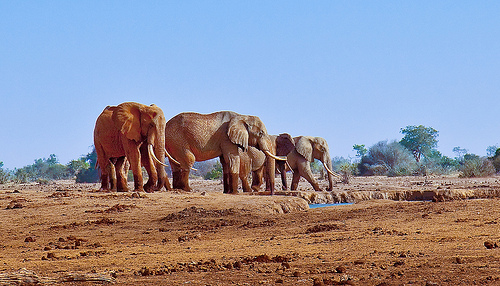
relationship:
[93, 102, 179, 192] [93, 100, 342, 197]
elephant in herd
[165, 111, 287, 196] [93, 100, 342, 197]
elephant in herd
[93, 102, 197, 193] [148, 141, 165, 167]
elephant has tusk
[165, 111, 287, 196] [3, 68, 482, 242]
elephant in jungle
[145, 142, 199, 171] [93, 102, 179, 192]
tusk of an elephant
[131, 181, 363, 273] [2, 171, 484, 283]
dirt on ground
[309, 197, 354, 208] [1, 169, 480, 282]
water in middle of desert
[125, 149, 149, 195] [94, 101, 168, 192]
leg of an elephant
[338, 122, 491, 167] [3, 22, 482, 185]
trees in background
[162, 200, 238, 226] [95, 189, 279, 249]
dirt of dirt